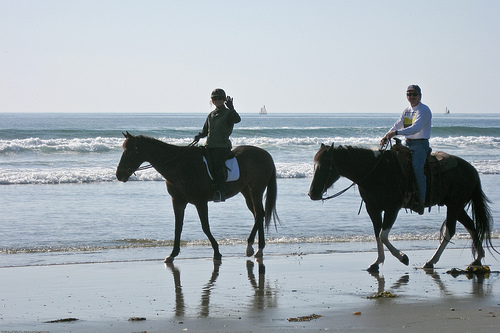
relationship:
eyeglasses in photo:
[213, 97, 226, 102] [1, 0, 499, 331]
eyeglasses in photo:
[406, 92, 421, 98] [1, 0, 499, 331]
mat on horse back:
[203, 149, 240, 183] [171, 144, 258, 165]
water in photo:
[0, 112, 499, 258] [1, 0, 499, 331]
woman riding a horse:
[192, 88, 241, 203] [116, 130, 279, 267]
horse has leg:
[116, 130, 279, 267] [192, 200, 221, 261]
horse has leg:
[116, 130, 279, 267] [166, 195, 188, 264]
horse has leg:
[116, 130, 279, 267] [250, 181, 265, 257]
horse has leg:
[116, 130, 279, 267] [242, 187, 255, 257]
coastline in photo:
[0, 234, 499, 272] [1, 0, 499, 331]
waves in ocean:
[1, 137, 499, 193] [0, 112, 499, 258]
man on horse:
[383, 85, 432, 214] [308, 142, 497, 274]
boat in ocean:
[258, 105, 268, 115] [0, 112, 499, 258]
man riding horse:
[383, 85, 432, 214] [308, 142, 497, 274]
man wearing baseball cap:
[383, 85, 432, 214] [407, 84, 420, 93]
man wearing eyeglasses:
[383, 85, 432, 214] [406, 92, 421, 98]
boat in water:
[258, 105, 268, 115] [0, 112, 499, 258]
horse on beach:
[116, 130, 279, 267] [0, 242, 499, 330]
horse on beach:
[308, 142, 497, 274] [0, 242, 499, 330]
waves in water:
[1, 137, 499, 193] [0, 112, 499, 258]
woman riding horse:
[192, 88, 241, 203] [116, 130, 279, 267]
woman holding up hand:
[192, 88, 241, 203] [225, 96, 235, 107]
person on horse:
[192, 88, 241, 203] [116, 130, 279, 267]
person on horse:
[383, 85, 432, 214] [308, 142, 497, 274]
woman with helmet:
[192, 88, 241, 203] [209, 89, 226, 98]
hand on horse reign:
[194, 134, 201, 142] [127, 138, 201, 178]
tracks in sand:
[48, 289, 397, 326] [0, 242, 499, 330]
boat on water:
[258, 105, 268, 115] [0, 112, 499, 258]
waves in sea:
[1, 137, 499, 193] [0, 112, 499, 258]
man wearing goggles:
[383, 85, 432, 214] [406, 92, 421, 98]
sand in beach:
[0, 242, 499, 330] [2, 111, 448, 331]